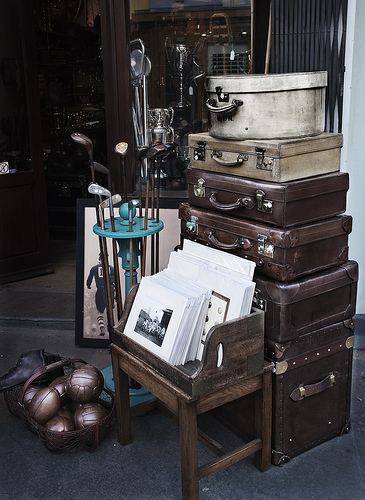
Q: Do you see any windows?
A: Yes, there is a window.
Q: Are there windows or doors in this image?
A: Yes, there is a window.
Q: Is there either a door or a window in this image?
A: Yes, there is a window.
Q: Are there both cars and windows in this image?
A: No, there is a window but no cars.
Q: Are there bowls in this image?
A: No, there are no bowls.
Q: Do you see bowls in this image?
A: No, there are no bowls.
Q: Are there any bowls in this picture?
A: No, there are no bowls.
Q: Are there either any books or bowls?
A: No, there are no bowls or books.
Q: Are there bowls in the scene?
A: No, there are no bowls.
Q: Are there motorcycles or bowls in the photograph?
A: No, there are no bowls or motorcycles.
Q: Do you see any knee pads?
A: No, there are no knee pads.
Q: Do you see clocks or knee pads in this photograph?
A: No, there are no knee pads or clocks.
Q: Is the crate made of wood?
A: Yes, the crate is made of wood.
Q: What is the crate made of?
A: The crate is made of wood.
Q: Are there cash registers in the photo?
A: No, there are no cash registers.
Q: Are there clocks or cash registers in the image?
A: No, there are no cash registers or clocks.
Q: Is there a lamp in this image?
A: No, there are no lamps.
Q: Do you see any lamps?
A: No, there are no lamps.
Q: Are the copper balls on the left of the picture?
A: Yes, the balls are on the left of the image.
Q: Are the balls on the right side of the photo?
A: No, the balls are on the left of the image.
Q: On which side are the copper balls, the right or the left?
A: The balls are on the left of the image.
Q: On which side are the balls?
A: The balls are on the left of the image.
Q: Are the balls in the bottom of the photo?
A: Yes, the balls are in the bottom of the image.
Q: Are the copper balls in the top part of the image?
A: No, the balls are in the bottom of the image.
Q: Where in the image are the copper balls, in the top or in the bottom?
A: The balls are in the bottom of the image.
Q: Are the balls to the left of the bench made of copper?
A: Yes, the balls are made of copper.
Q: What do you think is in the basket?
A: The balls are in the basket.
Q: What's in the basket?
A: The balls are in the basket.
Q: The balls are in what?
A: The balls are in the basket.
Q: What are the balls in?
A: The balls are in the basket.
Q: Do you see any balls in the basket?
A: Yes, there are balls in the basket.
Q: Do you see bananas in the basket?
A: No, there are balls in the basket.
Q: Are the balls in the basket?
A: Yes, the balls are in the basket.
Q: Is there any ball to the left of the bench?
A: Yes, there are balls to the left of the bench.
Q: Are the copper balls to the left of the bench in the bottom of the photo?
A: Yes, the balls are to the left of the bench.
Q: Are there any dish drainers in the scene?
A: No, there are no dish drainers.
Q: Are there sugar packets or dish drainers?
A: No, there are no dish drainers or sugar packets.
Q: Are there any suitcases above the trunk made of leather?
A: Yes, there is a suitcase above the trunk.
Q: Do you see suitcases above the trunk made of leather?
A: Yes, there is a suitcase above the trunk.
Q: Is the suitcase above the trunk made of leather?
A: Yes, the suitcase is above the trunk.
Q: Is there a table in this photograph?
A: Yes, there is a table.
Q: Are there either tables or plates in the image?
A: Yes, there is a table.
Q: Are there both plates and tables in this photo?
A: No, there is a table but no plates.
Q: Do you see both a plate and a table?
A: No, there is a table but no plates.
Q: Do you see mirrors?
A: No, there are no mirrors.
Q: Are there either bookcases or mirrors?
A: No, there are no mirrors or bookcases.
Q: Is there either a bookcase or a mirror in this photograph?
A: No, there are no mirrors or bookcases.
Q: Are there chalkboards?
A: No, there are no chalkboards.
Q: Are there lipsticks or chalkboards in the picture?
A: No, there are no chalkboards or lipsticks.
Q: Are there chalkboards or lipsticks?
A: No, there are no chalkboards or lipsticks.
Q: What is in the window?
A: The merchandise is in the window.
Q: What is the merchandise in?
A: The merchandise is in the window.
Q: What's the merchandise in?
A: The merchandise is in the window.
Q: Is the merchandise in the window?
A: Yes, the merchandise is in the window.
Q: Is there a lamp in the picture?
A: No, there are no lamps.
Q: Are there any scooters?
A: No, there are no scooters.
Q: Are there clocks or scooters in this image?
A: No, there are no scooters or clocks.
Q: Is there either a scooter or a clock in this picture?
A: No, there are no scooters or clocks.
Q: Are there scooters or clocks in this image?
A: No, there are no scooters or clocks.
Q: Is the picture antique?
A: Yes, the picture is antique.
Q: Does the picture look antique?
A: Yes, the picture is antique.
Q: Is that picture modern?
A: No, the picture is antique.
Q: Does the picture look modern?
A: No, the picture is antique.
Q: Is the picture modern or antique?
A: The picture is antique.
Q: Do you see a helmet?
A: No, there are no helmets.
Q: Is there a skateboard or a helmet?
A: No, there are no helmets or skateboards.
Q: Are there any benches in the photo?
A: Yes, there is a bench.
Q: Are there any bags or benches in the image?
A: Yes, there is a bench.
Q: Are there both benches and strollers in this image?
A: No, there is a bench but no strollers.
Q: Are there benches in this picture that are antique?
A: Yes, there is an antique bench.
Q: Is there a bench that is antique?
A: Yes, there is a bench that is antique.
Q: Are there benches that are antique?
A: Yes, there is a bench that is antique.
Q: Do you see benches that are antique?
A: Yes, there is a bench that is antique.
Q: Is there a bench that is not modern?
A: Yes, there is a antique bench.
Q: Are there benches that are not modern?
A: Yes, there is a antique bench.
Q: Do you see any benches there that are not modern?
A: Yes, there is a antique bench.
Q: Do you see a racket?
A: No, there are no rackets.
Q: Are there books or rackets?
A: No, there are no rackets or books.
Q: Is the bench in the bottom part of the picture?
A: Yes, the bench is in the bottom of the image.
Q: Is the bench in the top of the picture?
A: No, the bench is in the bottom of the image.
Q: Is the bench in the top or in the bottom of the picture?
A: The bench is in the bottom of the image.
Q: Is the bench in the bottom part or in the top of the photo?
A: The bench is in the bottom of the image.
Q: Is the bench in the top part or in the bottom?
A: The bench is in the bottom of the image.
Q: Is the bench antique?
A: Yes, the bench is antique.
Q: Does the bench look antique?
A: Yes, the bench is antique.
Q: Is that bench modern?
A: No, the bench is antique.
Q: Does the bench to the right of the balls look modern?
A: No, the bench is antique.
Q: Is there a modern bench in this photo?
A: No, there is a bench but it is antique.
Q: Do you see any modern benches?
A: No, there is a bench but it is antique.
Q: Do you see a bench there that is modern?
A: No, there is a bench but it is antique.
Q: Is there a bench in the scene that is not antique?
A: No, there is a bench but it is antique.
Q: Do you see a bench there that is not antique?
A: No, there is a bench but it is antique.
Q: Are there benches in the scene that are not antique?
A: No, there is a bench but it is antique.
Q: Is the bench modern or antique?
A: The bench is antique.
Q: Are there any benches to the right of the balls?
A: Yes, there is a bench to the right of the balls.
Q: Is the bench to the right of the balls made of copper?
A: Yes, the bench is to the right of the balls.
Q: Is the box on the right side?
A: Yes, the box is on the right of the image.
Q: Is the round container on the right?
A: Yes, the box is on the right of the image.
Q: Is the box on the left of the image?
A: No, the box is on the right of the image.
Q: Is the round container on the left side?
A: No, the box is on the right of the image.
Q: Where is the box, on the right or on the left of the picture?
A: The box is on the right of the image.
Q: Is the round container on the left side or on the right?
A: The box is on the right of the image.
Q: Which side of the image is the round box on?
A: The box is on the right of the image.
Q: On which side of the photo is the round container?
A: The box is on the right of the image.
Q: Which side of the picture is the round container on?
A: The box is on the right of the image.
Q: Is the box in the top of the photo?
A: Yes, the box is in the top of the image.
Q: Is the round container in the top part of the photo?
A: Yes, the box is in the top of the image.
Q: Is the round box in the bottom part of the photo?
A: No, the box is in the top of the image.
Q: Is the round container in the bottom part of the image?
A: No, the box is in the top of the image.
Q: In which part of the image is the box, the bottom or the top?
A: The box is in the top of the image.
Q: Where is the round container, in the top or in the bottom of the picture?
A: The box is in the top of the image.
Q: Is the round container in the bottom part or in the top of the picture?
A: The box is in the top of the image.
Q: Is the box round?
A: Yes, the box is round.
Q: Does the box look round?
A: Yes, the box is round.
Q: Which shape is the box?
A: The box is round.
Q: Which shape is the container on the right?
A: The box is round.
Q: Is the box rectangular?
A: No, the box is round.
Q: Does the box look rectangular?
A: No, the box is round.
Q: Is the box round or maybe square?
A: The box is round.